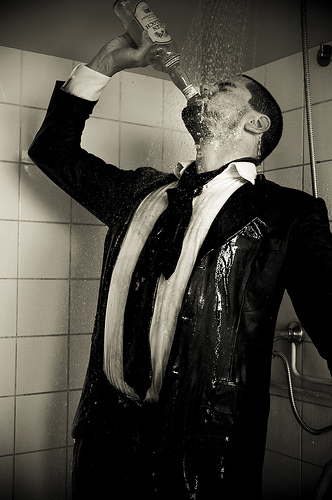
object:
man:
[28, 32, 332, 499]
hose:
[298, 10, 320, 191]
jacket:
[28, 80, 331, 487]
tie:
[121, 156, 262, 399]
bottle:
[111, 1, 204, 103]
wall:
[0, 0, 36, 497]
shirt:
[54, 61, 260, 407]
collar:
[173, 159, 261, 187]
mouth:
[187, 94, 204, 107]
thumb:
[123, 40, 155, 65]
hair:
[236, 68, 285, 164]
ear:
[245, 114, 272, 135]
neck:
[191, 144, 264, 172]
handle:
[277, 319, 306, 345]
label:
[132, 2, 174, 45]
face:
[182, 73, 247, 122]